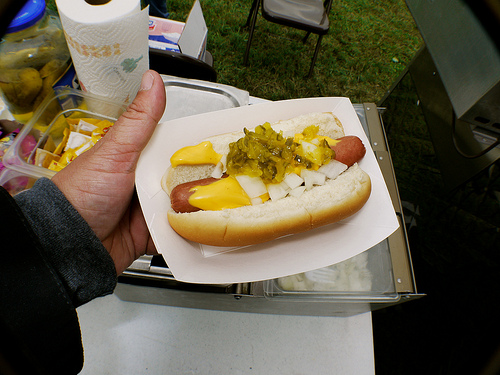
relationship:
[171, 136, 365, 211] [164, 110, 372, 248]
hot dog in bun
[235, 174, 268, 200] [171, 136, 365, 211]
onion on hot dog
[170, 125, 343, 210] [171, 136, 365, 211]
mustard on hot dog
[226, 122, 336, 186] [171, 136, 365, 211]
relish on hot dog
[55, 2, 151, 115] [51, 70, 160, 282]
paper towel next to hand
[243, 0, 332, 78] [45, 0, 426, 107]
chair on lawn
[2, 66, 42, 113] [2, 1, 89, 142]
pickle in jar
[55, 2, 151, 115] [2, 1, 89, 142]
paper towel next to jar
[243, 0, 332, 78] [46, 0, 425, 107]
chair in grass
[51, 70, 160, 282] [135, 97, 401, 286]
hand holding plate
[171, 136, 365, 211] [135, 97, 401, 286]
hot dog on plate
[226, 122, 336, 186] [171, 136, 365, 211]
relish on top of hot dog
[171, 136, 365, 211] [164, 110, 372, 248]
hot dog inside bun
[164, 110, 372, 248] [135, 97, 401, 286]
bun inside plate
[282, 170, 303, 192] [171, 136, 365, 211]
onion on hot dog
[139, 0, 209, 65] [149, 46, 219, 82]
box on chair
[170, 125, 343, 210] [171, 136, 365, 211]
mustard on top of hot dog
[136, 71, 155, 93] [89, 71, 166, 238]
nail on thumb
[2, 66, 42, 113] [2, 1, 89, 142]
pickle inside jar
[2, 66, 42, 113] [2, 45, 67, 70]
pickle next to pickle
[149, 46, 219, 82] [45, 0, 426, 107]
chair on lawn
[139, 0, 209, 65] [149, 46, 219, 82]
box on to of chair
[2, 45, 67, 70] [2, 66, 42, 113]
pickle on top of pickle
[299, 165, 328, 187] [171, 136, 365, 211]
onion on top of hot dog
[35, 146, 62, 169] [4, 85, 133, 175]
mustard in bin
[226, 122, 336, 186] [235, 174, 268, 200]
relish on onion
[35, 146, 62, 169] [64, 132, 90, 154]
mustard next to mustard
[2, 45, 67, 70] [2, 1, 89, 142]
pickle inside jar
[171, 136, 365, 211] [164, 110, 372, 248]
hot dog laying on bun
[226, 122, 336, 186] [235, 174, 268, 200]
relish on top of onion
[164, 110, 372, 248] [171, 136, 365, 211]
bun under hot dog